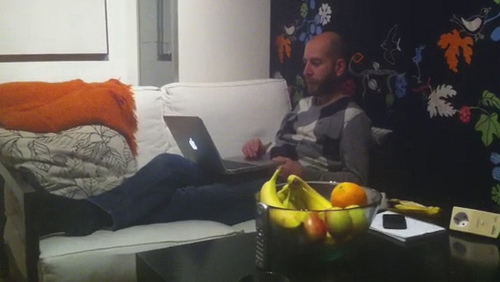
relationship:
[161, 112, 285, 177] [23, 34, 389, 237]
laptop on man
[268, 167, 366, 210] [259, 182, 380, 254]
fruit in bowl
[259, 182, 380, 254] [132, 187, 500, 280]
bowl on table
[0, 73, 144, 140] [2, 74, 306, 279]
blanket on couch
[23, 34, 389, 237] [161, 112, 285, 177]
man using laptop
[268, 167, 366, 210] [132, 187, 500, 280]
fruit on table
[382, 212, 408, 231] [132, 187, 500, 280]
cellphone on table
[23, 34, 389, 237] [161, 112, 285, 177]
man on laptop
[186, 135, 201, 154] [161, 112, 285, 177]
logo of laptop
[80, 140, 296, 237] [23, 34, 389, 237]
jeans on man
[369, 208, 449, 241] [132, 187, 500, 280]
notebook on table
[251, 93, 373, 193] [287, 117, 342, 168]
sweater has argyle design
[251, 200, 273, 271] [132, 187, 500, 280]
phone on table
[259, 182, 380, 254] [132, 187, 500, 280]
fruitbowl on table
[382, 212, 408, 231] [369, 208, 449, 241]
cellphone on tablet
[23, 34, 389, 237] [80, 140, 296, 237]
man wearing jeans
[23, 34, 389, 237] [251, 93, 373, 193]
man wearing sweater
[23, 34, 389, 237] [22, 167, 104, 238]
man wearing socks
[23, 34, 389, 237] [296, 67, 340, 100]
man has facial hair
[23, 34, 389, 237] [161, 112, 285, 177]
man holding laptop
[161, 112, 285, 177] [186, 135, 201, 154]
laptop has apple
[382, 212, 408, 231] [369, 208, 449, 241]
mobile phone on notebook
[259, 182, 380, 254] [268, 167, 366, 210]
bowl has fruit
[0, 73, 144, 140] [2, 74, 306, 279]
throw on couch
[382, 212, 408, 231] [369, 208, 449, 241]
cellphone on notebook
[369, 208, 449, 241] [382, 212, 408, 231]
papers under cellphone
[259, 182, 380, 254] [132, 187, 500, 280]
fruits on table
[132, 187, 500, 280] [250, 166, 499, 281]
table has various items